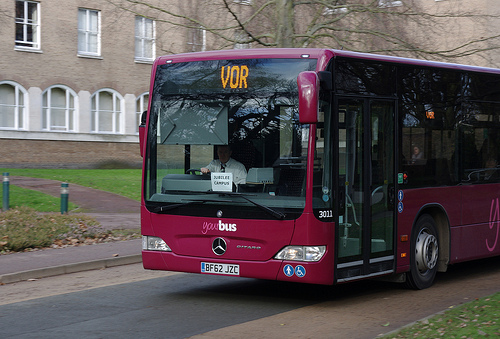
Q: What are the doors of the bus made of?
A: The doors are made of black and glass.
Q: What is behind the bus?
A: A tree without leaves.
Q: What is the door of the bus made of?
A: The front door of the bus is made of glass.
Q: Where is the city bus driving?
A: The City bus is driving down the road.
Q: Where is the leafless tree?
A: The leafless tree is behind the bus.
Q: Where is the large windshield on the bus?
A: The large windshield is in front of the bus.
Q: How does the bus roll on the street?
A: With tires.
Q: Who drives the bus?
A: The man.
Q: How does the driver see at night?
A: The headlights.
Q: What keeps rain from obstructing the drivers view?
A: Windshied wipers.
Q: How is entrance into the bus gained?
A: The doors.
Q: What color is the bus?
A: Red.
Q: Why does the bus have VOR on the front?
A: Identifies each stop.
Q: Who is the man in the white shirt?
A: Bus driver.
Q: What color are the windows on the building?
A: White.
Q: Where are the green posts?
A: Behind the bus.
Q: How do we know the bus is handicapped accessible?
A: Decal on front.